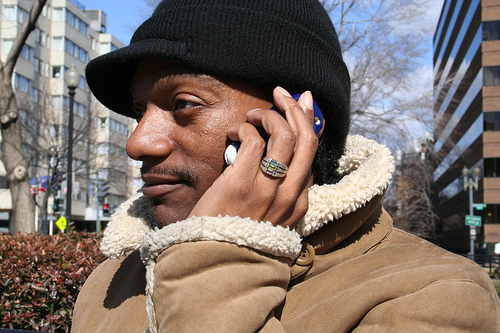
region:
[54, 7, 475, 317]
a man on his cell phone.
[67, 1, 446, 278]
person holding a cell phone.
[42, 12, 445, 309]
man using personal cell phone.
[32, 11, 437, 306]
a man holding his cellular phone.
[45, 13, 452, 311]
a man holding his cell phone during daytime.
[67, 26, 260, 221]
a man with mustache.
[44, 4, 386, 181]
man wearing a black hat.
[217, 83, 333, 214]
hand holding a cell phone.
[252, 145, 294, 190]
a large ring a person's finger.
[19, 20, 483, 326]
a man wearing a brown jacket.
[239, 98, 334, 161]
blue cell phone in hand.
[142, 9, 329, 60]
black stocking cap on head.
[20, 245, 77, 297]
bushes in the background.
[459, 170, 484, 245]
street signs on pole.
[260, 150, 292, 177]
ring on man's finger.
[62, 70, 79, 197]
black lamp post with lamp.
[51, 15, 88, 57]
tall building behind trees.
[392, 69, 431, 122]
white clouds in the sky.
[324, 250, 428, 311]
brown winter coat.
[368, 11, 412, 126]
bare tree branches.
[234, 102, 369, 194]
the phone is blue and white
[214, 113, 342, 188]
he is talking on the phone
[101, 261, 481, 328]
the jacket is brown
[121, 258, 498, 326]
the jacket is made of suede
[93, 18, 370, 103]
the marvin is black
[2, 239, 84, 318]
the bush has red leaves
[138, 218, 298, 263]
the lining of the jacket is white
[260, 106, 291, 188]
the ring is silver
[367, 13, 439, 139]
the sky is blue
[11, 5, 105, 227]
the building is in the background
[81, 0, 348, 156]
man wearing a black hat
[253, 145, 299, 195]
large ring on man's hand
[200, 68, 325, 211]
man holding phone up to his ear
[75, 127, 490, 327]
man is wearing a light brown coat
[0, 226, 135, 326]
red shrubbery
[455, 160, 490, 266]
pole with two lights on it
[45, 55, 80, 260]
tall streetlamp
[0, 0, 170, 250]
large building to the left of man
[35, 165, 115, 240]
traffic lights in front of building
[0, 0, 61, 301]
tree behind shrubbery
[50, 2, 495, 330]
Man talking in a cell phone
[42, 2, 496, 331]
Man wearing black cap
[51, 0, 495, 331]
Man wearing brown coat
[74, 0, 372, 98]
Hat is black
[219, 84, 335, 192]
Blue and white cell phone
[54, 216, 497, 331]
Coat has sheep wool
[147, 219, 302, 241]
Sheep wool of coat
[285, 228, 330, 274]
Brown button in a coat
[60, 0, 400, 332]
Man wearing a ring in his hand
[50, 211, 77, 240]
Yellow sign in a pole